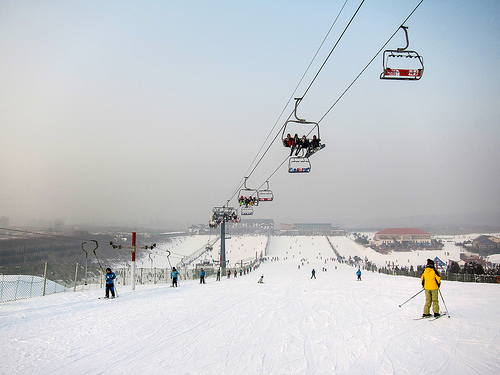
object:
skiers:
[257, 274, 265, 283]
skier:
[103, 268, 116, 299]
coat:
[105, 272, 116, 287]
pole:
[131, 231, 137, 290]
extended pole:
[399, 288, 425, 307]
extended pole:
[439, 289, 451, 319]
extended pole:
[111, 278, 119, 297]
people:
[356, 268, 362, 281]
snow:
[0, 230, 499, 375]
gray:
[0, 0, 499, 285]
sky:
[0, 0, 499, 238]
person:
[420, 258, 442, 317]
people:
[310, 135, 321, 150]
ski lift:
[206, 0, 429, 227]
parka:
[420, 265, 442, 291]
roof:
[374, 228, 432, 234]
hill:
[135, 234, 359, 285]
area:
[0, 212, 500, 373]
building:
[374, 227, 432, 240]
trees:
[353, 232, 444, 255]